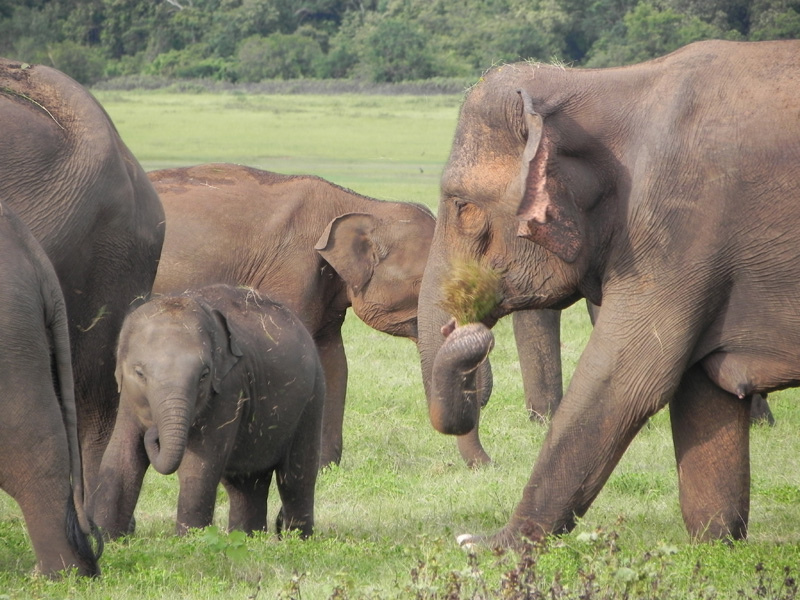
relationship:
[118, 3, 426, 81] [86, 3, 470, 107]
trees in area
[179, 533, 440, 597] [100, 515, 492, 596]
patch on ground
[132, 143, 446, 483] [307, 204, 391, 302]
elephant has ear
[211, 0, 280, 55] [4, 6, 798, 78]
tree in woods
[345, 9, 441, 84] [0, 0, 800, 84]
tree in area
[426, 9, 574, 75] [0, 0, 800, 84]
tree in area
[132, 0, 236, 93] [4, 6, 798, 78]
tree in woods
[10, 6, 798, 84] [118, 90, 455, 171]
forest behind field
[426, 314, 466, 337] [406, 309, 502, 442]
grass in trunk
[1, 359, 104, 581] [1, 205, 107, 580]
rear leg belonging to elephant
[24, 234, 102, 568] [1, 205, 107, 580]
tail belonging to elephant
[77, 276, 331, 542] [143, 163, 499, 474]
elephant walking in front of elephant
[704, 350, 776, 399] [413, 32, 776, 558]
breast belonging to elephant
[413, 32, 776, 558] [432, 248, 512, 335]
elephant eating grass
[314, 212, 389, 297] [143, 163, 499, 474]
ear belonging to elephant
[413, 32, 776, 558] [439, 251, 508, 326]
elephant eating grass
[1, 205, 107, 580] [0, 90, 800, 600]
elephant walking in field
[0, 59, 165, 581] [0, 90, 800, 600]
elephant walking in field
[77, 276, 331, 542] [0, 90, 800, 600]
elephant walking in field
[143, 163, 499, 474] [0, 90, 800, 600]
elephant walking in field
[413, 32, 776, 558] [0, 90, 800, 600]
elephant walking in field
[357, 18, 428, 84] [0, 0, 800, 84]
bush standing in area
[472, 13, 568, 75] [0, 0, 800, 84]
bush standing in area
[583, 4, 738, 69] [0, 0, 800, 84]
bush standing in area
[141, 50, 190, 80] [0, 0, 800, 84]
bush standing in area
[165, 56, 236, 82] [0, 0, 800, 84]
bush standing in area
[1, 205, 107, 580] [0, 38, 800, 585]
elephant belonging to elephants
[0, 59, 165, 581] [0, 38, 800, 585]
elephant belonging to elephants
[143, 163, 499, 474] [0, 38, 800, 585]
elephant belonging to elephants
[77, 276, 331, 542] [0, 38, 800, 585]
elephant belonging to elephants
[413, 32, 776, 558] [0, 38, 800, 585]
elephant belonging to elephants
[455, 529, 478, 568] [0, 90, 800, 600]
flower growing in field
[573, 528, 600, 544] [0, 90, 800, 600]
flower growing in field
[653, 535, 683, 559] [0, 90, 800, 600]
flower growing in field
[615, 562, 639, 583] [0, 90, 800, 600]
flower growing in field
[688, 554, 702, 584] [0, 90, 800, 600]
flower growing in field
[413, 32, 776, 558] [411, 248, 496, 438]
elephant curling trunk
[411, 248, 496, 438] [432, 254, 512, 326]
trunk holding grass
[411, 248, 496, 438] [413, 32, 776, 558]
trunk belonging to elephant